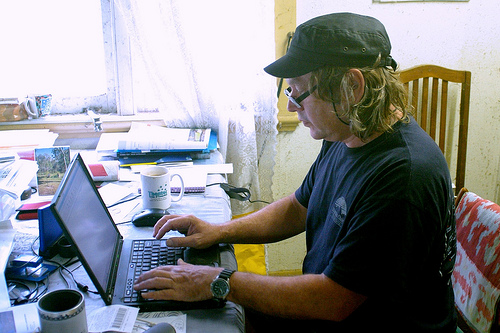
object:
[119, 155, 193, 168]
files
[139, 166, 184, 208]
mug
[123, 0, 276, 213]
curtain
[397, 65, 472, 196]
chair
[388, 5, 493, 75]
wall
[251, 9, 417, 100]
cap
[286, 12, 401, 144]
head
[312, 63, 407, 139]
hair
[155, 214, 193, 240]
fingers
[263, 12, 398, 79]
cap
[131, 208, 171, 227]
corded mouse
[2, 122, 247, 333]
desk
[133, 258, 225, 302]
hand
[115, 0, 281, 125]
screen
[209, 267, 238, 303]
watch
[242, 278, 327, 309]
hair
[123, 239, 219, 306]
keyboard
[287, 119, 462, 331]
t-shirt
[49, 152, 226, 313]
laptop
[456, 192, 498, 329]
blanket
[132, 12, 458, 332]
man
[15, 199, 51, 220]
wallet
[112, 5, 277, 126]
window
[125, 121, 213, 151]
books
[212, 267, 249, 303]
wrist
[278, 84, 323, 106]
reading glasses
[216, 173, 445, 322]
arm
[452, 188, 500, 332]
chair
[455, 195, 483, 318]
cloth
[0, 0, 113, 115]
window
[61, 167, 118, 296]
screen